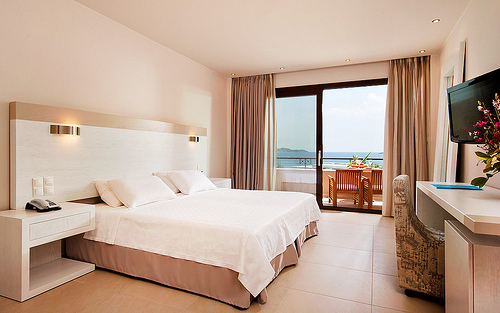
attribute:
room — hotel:
[47, 31, 434, 278]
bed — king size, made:
[60, 165, 320, 309]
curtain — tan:
[229, 72, 276, 189]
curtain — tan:
[383, 55, 428, 217]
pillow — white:
[106, 172, 178, 210]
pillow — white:
[93, 179, 124, 207]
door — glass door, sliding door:
[304, 82, 400, 223]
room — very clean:
[7, 5, 495, 310]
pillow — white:
[108, 173, 177, 206]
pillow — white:
[94, 182, 119, 206]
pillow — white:
[157, 170, 180, 192]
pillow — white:
[167, 167, 217, 194]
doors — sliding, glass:
[263, 76, 388, 216]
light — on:
[189, 135, 199, 142]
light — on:
[47, 122, 80, 136]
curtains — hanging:
[229, 56, 427, 220]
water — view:
[296, 156, 346, 166]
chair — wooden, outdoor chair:
[328, 166, 363, 208]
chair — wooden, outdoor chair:
[362, 168, 383, 208]